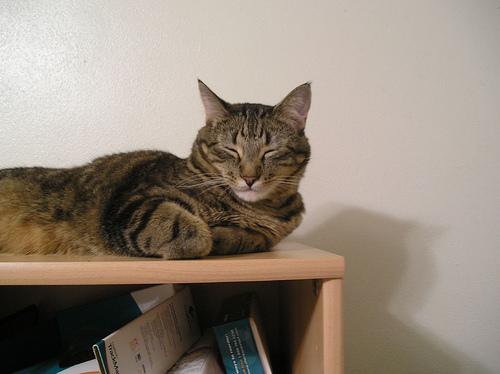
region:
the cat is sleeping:
[43, 80, 369, 307]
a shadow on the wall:
[280, 159, 436, 371]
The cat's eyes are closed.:
[221, 136, 278, 168]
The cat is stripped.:
[111, 171, 173, 234]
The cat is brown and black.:
[104, 168, 181, 231]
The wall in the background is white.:
[64, 53, 155, 105]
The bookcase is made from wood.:
[288, 295, 317, 354]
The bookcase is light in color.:
[296, 297, 321, 360]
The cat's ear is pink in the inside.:
[281, 81, 311, 123]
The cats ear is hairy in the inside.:
[276, 79, 314, 122]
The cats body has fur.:
[17, 176, 127, 239]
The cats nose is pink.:
[243, 172, 255, 186]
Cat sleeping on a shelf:
[18, 61, 336, 257]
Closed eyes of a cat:
[208, 134, 290, 161]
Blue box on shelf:
[203, 308, 278, 373]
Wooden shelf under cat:
[41, 257, 356, 286]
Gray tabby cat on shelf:
[192, 73, 324, 198]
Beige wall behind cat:
[353, 43, 474, 238]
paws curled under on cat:
[138, 213, 226, 259]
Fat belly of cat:
[3, 212, 104, 260]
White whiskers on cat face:
[171, 169, 324, 200]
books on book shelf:
[48, 290, 291, 370]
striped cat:
[0, 78, 311, 258]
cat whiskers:
[177, 172, 315, 197]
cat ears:
[194, 78, 312, 127]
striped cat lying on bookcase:
[0, 82, 344, 372]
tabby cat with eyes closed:
[0, 79, 312, 264]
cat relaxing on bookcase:
[0, 78, 342, 372]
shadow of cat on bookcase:
[300, 208, 482, 369]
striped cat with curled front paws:
[0, 78, 310, 261]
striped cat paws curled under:
[153, 210, 266, 257]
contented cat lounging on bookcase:
[1, 77, 346, 373]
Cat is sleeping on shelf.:
[1, 76, 311, 256]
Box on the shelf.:
[210, 291, 272, 368]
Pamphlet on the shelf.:
[90, 306, 200, 367]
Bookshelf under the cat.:
[1, 246, 343, 371]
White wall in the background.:
[3, 2, 495, 372]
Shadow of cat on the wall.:
[303, 197, 448, 372]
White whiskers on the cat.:
[176, 164, 328, 214]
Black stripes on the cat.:
[114, 95, 314, 256]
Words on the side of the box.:
[216, 322, 258, 372]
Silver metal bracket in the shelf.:
[306, 278, 322, 296]